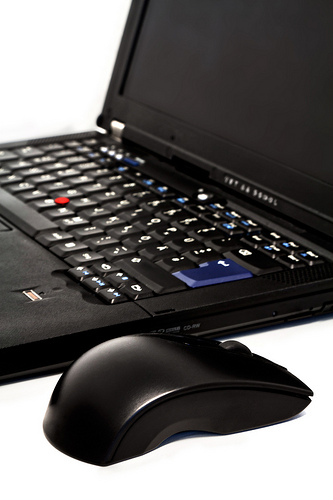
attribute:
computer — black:
[5, 10, 332, 394]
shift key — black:
[125, 253, 184, 293]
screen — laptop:
[113, 1, 330, 252]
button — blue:
[173, 259, 251, 288]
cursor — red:
[57, 196, 69, 207]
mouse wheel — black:
[210, 333, 254, 367]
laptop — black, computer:
[0, 1, 333, 386]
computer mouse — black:
[60, 341, 308, 442]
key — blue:
[175, 259, 258, 288]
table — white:
[176, 436, 328, 487]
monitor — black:
[95, 1, 330, 242]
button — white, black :
[292, 241, 311, 264]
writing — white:
[147, 320, 204, 332]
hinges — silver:
[106, 118, 127, 145]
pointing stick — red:
[54, 191, 67, 207]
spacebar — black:
[7, 185, 59, 244]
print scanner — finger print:
[17, 283, 43, 304]